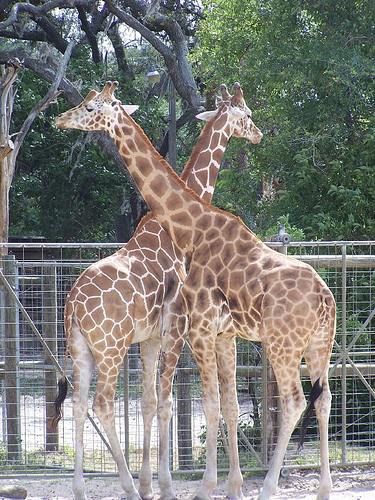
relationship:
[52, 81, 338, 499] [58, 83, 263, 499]
giraffe next to giraffe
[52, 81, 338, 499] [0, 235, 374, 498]
giraffe inside pen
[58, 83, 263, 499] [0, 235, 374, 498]
giraffe inside pen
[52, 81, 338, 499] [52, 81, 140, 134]
giraffe has head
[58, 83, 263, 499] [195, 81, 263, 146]
giraffe has head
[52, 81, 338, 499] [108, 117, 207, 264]
giraffe has neck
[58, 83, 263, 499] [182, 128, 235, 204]
giraffe has neck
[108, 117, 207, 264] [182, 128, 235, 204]
neck crossing neck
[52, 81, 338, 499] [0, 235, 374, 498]
giraffe enclosed in pen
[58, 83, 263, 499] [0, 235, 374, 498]
giraffe enclosed in pen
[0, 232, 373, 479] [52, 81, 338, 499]
fence behind giraffe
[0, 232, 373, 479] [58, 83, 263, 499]
fence behind giraffe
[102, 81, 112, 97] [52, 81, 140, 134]
horn on top of head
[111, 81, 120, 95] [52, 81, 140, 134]
horn on top of head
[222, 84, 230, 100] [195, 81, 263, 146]
horn on top of head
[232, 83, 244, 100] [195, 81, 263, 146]
horn on top of head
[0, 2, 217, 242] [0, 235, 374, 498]
tree behind pen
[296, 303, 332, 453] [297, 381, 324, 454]
tail has hair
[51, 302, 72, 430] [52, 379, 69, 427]
tail has hair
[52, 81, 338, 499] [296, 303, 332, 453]
giraffe has tail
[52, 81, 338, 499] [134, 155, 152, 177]
giraffe has spot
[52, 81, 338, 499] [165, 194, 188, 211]
giraffe has spot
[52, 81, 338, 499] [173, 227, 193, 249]
giraffe has spot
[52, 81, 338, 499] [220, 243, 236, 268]
giraffe has spot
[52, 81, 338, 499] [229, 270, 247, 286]
giraffe has spot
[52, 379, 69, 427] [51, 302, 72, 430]
hair growing from tail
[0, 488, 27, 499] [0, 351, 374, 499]
rock on top of ground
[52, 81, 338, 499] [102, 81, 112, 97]
giraffe has horn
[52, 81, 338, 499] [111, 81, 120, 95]
giraffe has horn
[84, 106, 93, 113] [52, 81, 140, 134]
eye located on head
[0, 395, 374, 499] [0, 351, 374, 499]
dirt on top of ground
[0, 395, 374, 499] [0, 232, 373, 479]
dirt near fence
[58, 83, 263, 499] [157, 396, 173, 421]
giraffe has knee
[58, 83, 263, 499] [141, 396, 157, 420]
giraffe has knee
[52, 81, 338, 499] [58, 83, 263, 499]
giraffe standing beside giraffe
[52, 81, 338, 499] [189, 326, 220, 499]
giraffe has leg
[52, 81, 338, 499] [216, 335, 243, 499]
giraffe has leg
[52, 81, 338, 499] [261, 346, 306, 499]
giraffe has leg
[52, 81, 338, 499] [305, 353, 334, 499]
giraffe has leg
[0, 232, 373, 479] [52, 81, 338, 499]
fence in front of giraffe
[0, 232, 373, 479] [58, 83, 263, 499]
fence in front of giraffe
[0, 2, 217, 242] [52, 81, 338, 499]
tree behind giraffe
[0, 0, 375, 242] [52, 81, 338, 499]
tree behind giraffe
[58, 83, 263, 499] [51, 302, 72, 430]
giraffe has tail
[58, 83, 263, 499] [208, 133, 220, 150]
giraffe has spot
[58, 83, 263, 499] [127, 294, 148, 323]
giraffe has spot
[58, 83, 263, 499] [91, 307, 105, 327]
giraffe has spot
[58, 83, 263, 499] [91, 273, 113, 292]
giraffe has spot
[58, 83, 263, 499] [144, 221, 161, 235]
giraffe has spot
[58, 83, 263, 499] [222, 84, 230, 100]
giraffe has horn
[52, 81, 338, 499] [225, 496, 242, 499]
giraffe has hoof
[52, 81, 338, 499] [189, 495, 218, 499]
giraffe has hoof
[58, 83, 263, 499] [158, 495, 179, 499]
giraffe has hoof